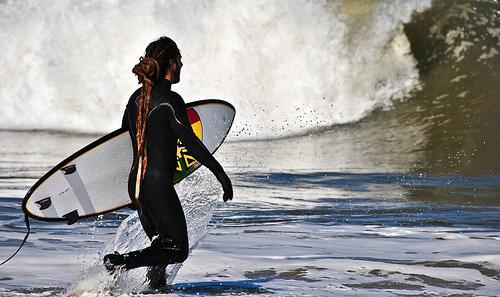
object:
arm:
[168, 95, 236, 173]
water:
[0, 1, 497, 293]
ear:
[169, 58, 175, 71]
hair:
[127, 36, 179, 181]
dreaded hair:
[128, 36, 178, 180]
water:
[281, 125, 488, 260]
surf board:
[21, 98, 237, 226]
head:
[143, 37, 183, 84]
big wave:
[2, 0, 432, 144]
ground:
[398, 203, 448, 270]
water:
[10, 0, 480, 157]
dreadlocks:
[131, 36, 175, 180]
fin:
[60, 164, 77, 175]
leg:
[105, 241, 190, 270]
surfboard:
[21, 99, 237, 225]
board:
[19, 99, 236, 224]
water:
[254, 145, 438, 267]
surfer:
[102, 36, 232, 293]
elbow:
[178, 138, 209, 164]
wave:
[0, 1, 498, 138]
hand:
[216, 170, 233, 203]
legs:
[102, 167, 189, 292]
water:
[292, 201, 473, 295]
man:
[104, 37, 232, 291]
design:
[172, 104, 203, 184]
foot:
[152, 229, 177, 254]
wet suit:
[120, 80, 233, 294]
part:
[223, 185, 231, 190]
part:
[224, 178, 227, 185]